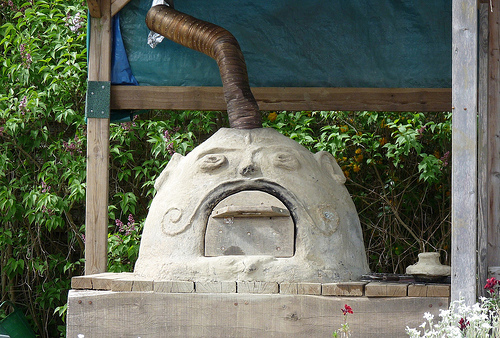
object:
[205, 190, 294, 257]
door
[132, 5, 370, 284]
furnace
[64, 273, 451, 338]
shelf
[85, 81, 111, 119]
bracket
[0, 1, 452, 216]
foliage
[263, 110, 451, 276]
trees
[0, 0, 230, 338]
bush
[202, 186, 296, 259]
mouth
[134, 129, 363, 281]
face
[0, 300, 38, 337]
bucket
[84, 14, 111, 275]
post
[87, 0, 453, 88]
blue tarp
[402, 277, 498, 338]
flowers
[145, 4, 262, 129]
pipe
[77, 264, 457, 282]
table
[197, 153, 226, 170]
eye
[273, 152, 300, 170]
eye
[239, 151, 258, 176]
nose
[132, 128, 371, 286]
head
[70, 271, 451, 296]
boards